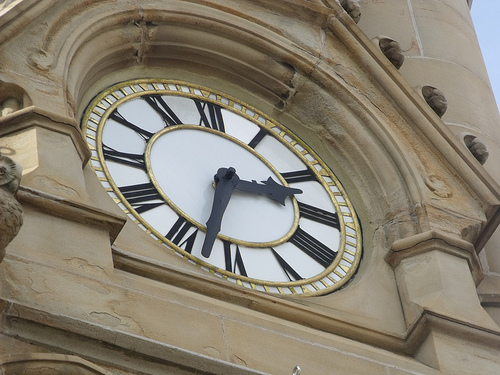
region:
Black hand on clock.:
[205, 168, 257, 261]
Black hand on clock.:
[243, 167, 308, 199]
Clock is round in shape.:
[121, 87, 338, 257]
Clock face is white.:
[110, 83, 322, 240]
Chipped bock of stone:
[88, 298, 137, 343]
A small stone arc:
[3, 350, 109, 369]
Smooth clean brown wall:
[367, 276, 399, 320]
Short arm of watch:
[241, 173, 307, 205]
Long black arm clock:
[211, 172, 231, 223]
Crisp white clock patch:
[166, 142, 196, 178]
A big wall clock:
[90, 81, 368, 278]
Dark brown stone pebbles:
[378, 29, 418, 74]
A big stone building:
[2, 183, 499, 349]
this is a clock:
[78, 60, 370, 307]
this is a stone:
[462, 115, 497, 199]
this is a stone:
[419, 70, 454, 124]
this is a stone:
[377, 24, 418, 79]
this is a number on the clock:
[290, 225, 335, 285]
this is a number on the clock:
[289, 189, 346, 236]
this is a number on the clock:
[221, 220, 262, 285]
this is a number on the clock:
[159, 200, 214, 278]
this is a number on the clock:
[127, 172, 169, 224]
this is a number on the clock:
[101, 135, 154, 187]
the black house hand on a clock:
[237, 175, 297, 203]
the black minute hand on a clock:
[204, 171, 239, 258]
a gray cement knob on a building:
[462, 127, 490, 171]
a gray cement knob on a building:
[423, 77, 454, 116]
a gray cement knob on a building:
[377, 28, 417, 70]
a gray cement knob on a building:
[342, 0, 368, 25]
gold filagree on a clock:
[108, 80, 229, 107]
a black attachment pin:
[226, 162, 245, 178]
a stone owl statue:
[1, 157, 26, 252]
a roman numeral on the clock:
[97, 136, 153, 174]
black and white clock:
[76, 46, 376, 311]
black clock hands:
[189, 152, 310, 262]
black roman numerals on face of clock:
[137, 87, 189, 131]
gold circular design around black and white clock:
[77, 75, 369, 302]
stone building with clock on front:
[0, 1, 497, 373]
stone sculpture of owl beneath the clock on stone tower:
[0, 151, 32, 259]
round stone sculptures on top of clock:
[340, 0, 499, 168]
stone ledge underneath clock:
[114, 231, 416, 351]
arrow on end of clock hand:
[263, 168, 310, 210]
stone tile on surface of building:
[356, 0, 498, 145]